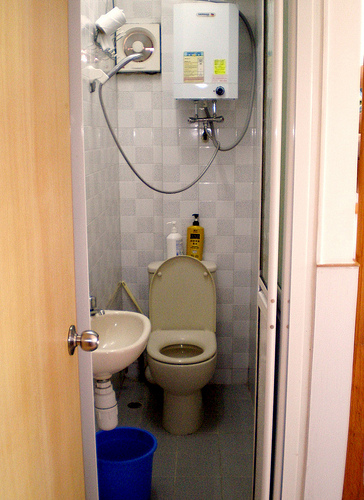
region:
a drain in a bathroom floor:
[123, 395, 141, 411]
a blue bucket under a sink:
[95, 419, 156, 491]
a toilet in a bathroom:
[141, 261, 217, 433]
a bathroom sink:
[88, 298, 153, 441]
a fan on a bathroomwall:
[114, 19, 161, 76]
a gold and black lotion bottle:
[183, 205, 206, 260]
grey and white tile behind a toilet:
[128, 122, 246, 250]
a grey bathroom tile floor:
[179, 428, 250, 497]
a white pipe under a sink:
[94, 375, 126, 434]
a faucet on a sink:
[88, 288, 107, 321]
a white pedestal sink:
[92, 293, 148, 434]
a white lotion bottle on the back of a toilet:
[166, 216, 183, 263]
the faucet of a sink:
[87, 292, 105, 321]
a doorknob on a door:
[67, 323, 96, 353]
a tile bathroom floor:
[108, 383, 253, 495]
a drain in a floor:
[127, 397, 144, 410]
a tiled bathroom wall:
[133, 128, 199, 199]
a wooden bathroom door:
[2, 1, 87, 497]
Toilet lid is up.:
[142, 267, 216, 335]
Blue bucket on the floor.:
[89, 420, 169, 497]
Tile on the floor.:
[173, 446, 266, 499]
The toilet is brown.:
[142, 261, 227, 397]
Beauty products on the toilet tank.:
[157, 211, 209, 260]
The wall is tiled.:
[99, 174, 219, 231]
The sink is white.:
[84, 301, 153, 370]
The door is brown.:
[5, 237, 81, 479]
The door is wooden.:
[8, 291, 68, 385]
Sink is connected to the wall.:
[83, 281, 144, 437]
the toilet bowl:
[143, 250, 225, 437]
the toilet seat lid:
[147, 256, 215, 330]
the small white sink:
[89, 303, 150, 369]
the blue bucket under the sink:
[102, 422, 156, 498]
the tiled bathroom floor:
[166, 437, 247, 497]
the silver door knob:
[68, 325, 97, 357]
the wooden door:
[3, 199, 59, 467]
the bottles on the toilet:
[162, 207, 205, 257]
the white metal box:
[173, 3, 240, 105]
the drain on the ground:
[125, 393, 143, 410]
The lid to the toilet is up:
[136, 260, 246, 387]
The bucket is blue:
[94, 424, 136, 481]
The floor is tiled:
[162, 414, 224, 497]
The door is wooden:
[12, 265, 80, 462]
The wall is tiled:
[105, 119, 220, 255]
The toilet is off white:
[158, 360, 220, 454]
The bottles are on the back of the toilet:
[131, 194, 259, 300]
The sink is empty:
[85, 301, 170, 421]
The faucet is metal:
[87, 295, 109, 324]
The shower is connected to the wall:
[87, 12, 179, 186]